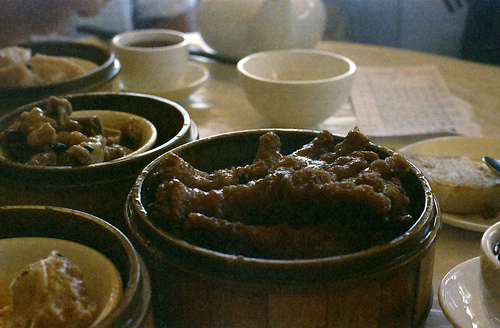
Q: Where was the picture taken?
A: In a restaurant.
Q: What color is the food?
A: Brown.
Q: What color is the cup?
A: White.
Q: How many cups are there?
A: Two.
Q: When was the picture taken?
A: Afternoon.